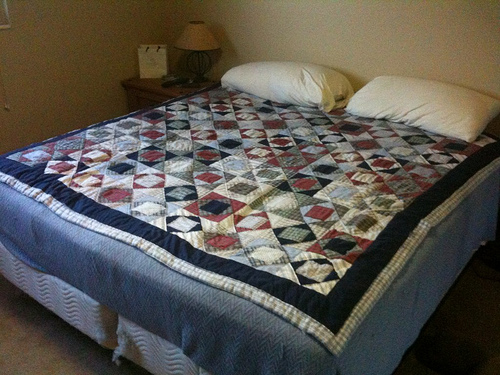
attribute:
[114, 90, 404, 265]
bed — cover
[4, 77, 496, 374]
beds — pushed together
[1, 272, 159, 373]
carpet — beige 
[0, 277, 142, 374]
carpet — tan 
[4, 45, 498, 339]
quilt — patterned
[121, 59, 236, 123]
table — wooden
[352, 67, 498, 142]
pillow — white 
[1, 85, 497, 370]
blanket — blue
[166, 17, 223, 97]
lamp — white shade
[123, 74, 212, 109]
nightstand — brown wood 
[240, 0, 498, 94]
wall — white 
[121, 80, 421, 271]
cover — bed , blue 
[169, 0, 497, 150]
tan wall — tan 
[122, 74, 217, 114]
table — bedside 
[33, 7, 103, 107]
wall — clean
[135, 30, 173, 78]
bag — white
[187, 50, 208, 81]
base — black metal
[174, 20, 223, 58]
shade — white 